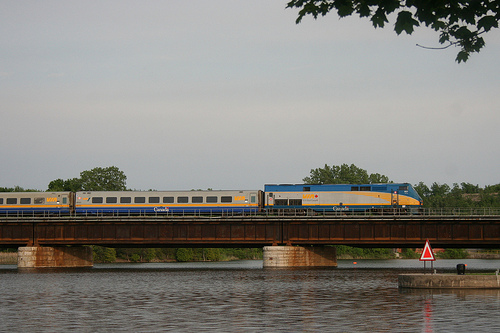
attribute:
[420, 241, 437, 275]
sign — triangular, red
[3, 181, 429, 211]
train — blue yellow silver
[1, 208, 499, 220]
fencing — silver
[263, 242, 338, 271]
pillar — brick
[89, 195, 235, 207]
windows — dark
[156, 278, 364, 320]
water — brownish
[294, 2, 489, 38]
leaves — green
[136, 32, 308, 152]
sky — light(ly) dark, dark, blue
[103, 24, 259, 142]
sky — dark